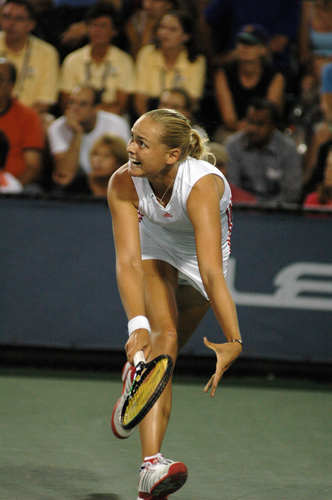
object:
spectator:
[225, 98, 303, 209]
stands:
[0, 0, 332, 198]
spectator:
[47, 83, 129, 186]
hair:
[144, 107, 217, 165]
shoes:
[110, 361, 189, 500]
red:
[168, 471, 183, 486]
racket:
[120, 348, 173, 431]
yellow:
[123, 358, 167, 425]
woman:
[105, 107, 242, 500]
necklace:
[156, 179, 174, 202]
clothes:
[132, 156, 233, 301]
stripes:
[226, 202, 233, 253]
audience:
[214, 25, 285, 129]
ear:
[166, 148, 179, 165]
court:
[10, 350, 324, 499]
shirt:
[47, 109, 130, 175]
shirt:
[135, 44, 206, 99]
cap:
[236, 24, 267, 44]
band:
[128, 315, 152, 336]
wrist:
[126, 314, 153, 335]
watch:
[230, 339, 243, 346]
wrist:
[225, 333, 244, 353]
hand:
[124, 328, 152, 364]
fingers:
[204, 375, 221, 399]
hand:
[203, 336, 242, 398]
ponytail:
[188, 129, 207, 162]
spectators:
[0, 0, 59, 112]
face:
[126, 113, 164, 176]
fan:
[59, 4, 134, 115]